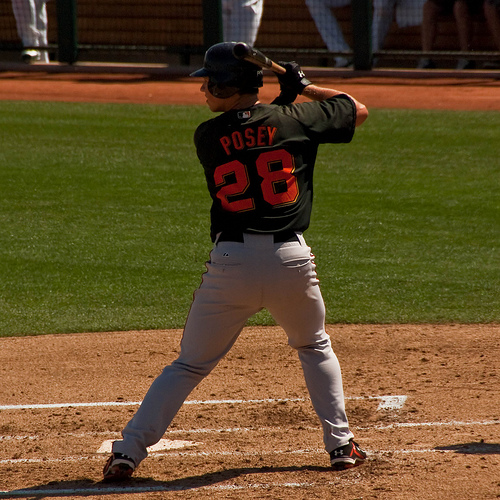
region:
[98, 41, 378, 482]
A baseball player preparing to bat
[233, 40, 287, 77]
A baseball bat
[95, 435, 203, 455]
A baseball plate on the ground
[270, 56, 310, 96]
A pair of black gloves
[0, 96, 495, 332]
A grassy field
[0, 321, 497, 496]
A patch of dirt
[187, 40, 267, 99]
a black baseball helmet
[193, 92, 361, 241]
A black and orange baseball jersey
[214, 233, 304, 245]
a black belt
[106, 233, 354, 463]
a pair of grey baseball pants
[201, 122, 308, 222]
this is Buster Posey of the SF Giants baseball team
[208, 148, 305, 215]
Posey's jersey number is 28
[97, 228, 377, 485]
Posey crouches to reduce the strike zone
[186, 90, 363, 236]
the black jersey indicates San Francisco is the visiting team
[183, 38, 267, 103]
Posey is wearing a batter's helmet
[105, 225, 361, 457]
Posey's uniform pants are gray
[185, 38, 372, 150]
Posey is batting right-handed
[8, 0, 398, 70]
players watch from the dugout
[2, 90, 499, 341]
the grass on a ball field is immaculately kept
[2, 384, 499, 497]
all the cleat marks indicate we are several innings in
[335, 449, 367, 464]
a base ball player with sneakers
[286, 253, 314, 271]
the hind pocket of a baseball player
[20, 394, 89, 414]
a white line on the base ball pitch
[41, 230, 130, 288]
green grass in the baseball pitch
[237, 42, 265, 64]
a baseball bat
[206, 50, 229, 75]
a base ball helmet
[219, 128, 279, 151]
a baseball jersey written on posey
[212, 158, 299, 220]
a baseball jersey written on number 28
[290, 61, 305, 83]
black gloves worn by the player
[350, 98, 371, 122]
the elbow of the player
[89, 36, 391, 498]
batter standing in batter's box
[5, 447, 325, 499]
shadow of batter on the dirt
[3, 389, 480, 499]
white lines of the batter's box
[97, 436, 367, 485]
black, orange, and white cleats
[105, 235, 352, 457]
gray pants batter is wearing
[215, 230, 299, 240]
black belt of the batter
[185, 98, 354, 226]
batter's black jersey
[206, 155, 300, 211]
orange numbers on black background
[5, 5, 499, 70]
players standing in the dugout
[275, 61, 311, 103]
black batting gloves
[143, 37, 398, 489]
The man is a baseball player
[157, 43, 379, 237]
The man is holding a bat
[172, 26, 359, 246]
The baseball player is holding a bat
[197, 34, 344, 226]
The baseball player is getting ready to swing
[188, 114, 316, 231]
The jersey saids Posey 28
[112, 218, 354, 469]
The baseball player's pants are grey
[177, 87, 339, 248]
The baseball player's shirt is black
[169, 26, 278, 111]
The baseball player's helmet is black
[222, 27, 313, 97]
The bat is black and wooden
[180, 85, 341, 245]
The jersey is black and orange